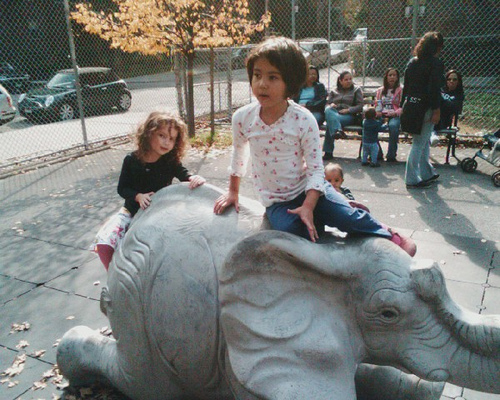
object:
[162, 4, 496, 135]
fence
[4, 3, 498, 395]
playground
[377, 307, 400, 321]
eye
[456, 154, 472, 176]
ground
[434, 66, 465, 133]
sitting women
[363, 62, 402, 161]
sitting women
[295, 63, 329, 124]
sitting women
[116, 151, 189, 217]
black shirt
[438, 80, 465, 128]
black shirt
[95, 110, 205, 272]
girl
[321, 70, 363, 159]
girl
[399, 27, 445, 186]
girl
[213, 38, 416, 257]
child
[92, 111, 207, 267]
child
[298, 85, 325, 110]
shirt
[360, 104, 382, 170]
toddler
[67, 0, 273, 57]
leaves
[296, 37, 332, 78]
car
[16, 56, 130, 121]
car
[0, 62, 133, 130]
two cars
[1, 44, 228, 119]
road side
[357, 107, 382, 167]
child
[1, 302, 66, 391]
leaves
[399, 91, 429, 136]
black bag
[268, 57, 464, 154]
women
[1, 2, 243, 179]
fence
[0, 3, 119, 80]
park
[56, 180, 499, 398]
elephant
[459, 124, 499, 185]
stroller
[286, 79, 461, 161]
bench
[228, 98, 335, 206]
shirt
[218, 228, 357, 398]
ear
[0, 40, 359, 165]
street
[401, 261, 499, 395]
trunk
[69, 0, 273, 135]
tree